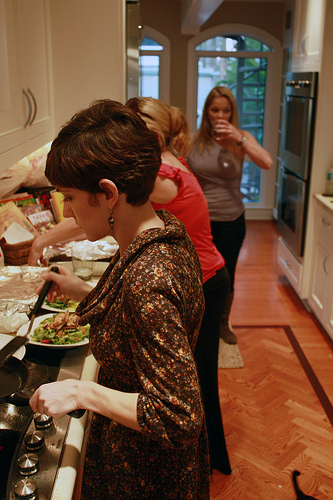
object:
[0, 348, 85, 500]
stove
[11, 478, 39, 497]
knob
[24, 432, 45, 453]
knob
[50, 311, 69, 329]
food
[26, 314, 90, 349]
plate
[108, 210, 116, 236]
earring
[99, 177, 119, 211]
ear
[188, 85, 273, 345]
woman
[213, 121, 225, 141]
glass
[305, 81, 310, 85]
knob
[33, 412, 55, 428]
knob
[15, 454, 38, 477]
knob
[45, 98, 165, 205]
hair